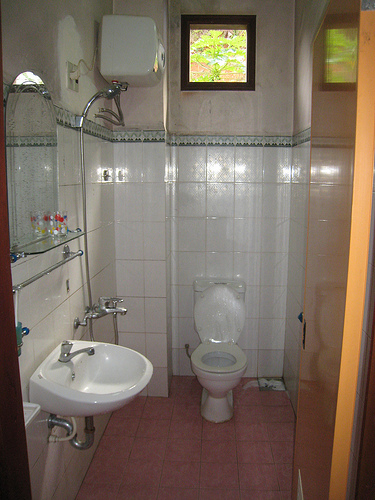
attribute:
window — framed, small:
[179, 15, 257, 88]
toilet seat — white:
[194, 343, 244, 371]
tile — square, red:
[242, 446, 285, 468]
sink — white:
[31, 340, 153, 420]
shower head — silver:
[80, 85, 118, 123]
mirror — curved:
[6, 72, 83, 256]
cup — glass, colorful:
[50, 211, 68, 238]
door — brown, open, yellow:
[298, 2, 373, 500]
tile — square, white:
[137, 185, 169, 212]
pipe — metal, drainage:
[50, 412, 97, 453]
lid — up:
[194, 287, 239, 342]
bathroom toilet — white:
[192, 279, 247, 420]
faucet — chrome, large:
[61, 340, 94, 361]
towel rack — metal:
[10, 245, 88, 291]